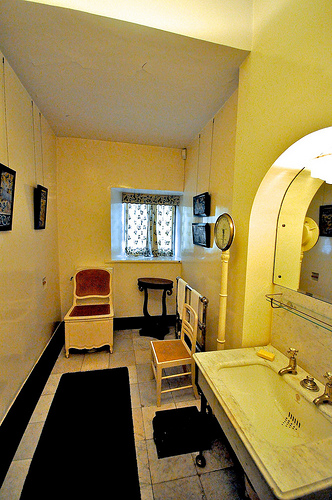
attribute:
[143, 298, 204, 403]
chair — white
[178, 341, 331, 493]
sink — white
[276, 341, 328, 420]
faucet — silver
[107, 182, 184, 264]
window — small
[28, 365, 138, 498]
rug — black, rectangle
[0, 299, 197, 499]
floor — tile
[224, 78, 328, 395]
wall — yellow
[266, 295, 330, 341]
shelf — glass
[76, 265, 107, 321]
cushions — red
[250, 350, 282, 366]
soap — yellow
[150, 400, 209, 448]
scale — black, old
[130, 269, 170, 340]
table — brown